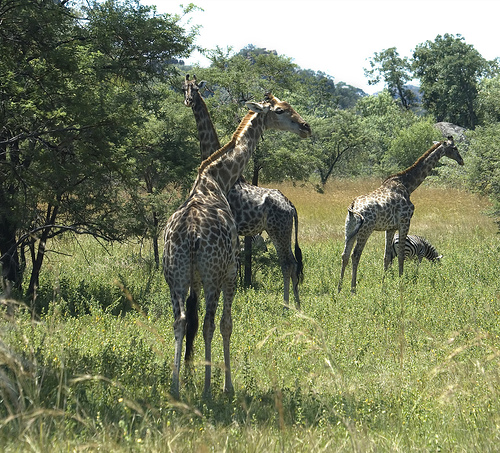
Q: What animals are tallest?
A: The giraffes.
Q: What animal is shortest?
A: The zebra.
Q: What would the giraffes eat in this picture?
A: Leaves and fruits from the trees.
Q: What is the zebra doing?
A: Grazing in the grass field.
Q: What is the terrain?
A: A flat field of grass and green leafy plants with many tall and leafy trees.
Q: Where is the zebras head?
A: Down in the grass trying to eat.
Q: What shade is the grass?
A: Green.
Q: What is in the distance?
A: Trees.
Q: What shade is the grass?
A: Green.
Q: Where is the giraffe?
A: In the field.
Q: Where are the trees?
A: Behind the giraffes.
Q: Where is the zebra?
A: Behind the giraffe.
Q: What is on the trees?
A: Leaves.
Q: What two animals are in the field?
A: Giraffes and a zebra.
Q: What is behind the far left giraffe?
A: A zebra.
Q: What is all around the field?
A: Trees.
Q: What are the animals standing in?
A: Grass.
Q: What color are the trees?
A: Green.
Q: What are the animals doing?
A: Grazing.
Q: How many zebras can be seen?
A: One.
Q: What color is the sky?
A: Blue.